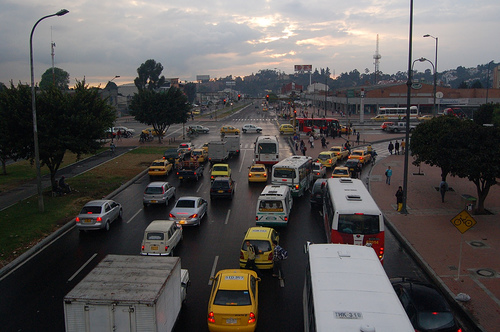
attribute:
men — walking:
[230, 233, 290, 298]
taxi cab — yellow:
[202, 263, 264, 328]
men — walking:
[243, 239, 258, 271]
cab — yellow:
[200, 261, 270, 330]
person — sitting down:
[54, 177, 76, 200]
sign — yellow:
[419, 183, 490, 260]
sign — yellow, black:
[437, 203, 478, 240]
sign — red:
[290, 52, 320, 74]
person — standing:
[268, 235, 287, 286]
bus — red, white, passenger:
[320, 176, 387, 262]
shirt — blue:
[384, 169, 391, 179]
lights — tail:
[203, 305, 259, 325]